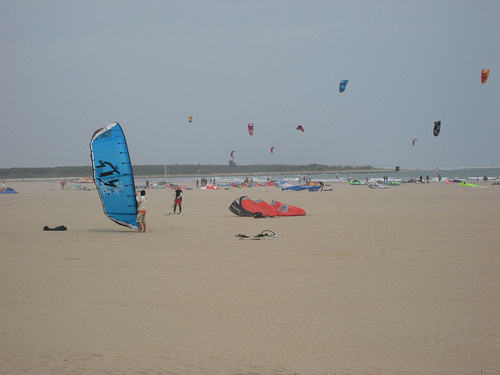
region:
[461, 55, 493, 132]
Large kite flying in sky.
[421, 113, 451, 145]
Large kite flying in sky.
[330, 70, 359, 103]
Large kite flying in sky.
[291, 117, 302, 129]
Large kite flying in the sky.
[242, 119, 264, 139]
Large kite flying in the sky.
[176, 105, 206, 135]
Large kite flying in the sky.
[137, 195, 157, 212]
Person wearing white shirt.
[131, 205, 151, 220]
Person wearing tan pants.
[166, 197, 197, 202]
Person wearing orange shorts.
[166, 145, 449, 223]
Many people on beach flying kites.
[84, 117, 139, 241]
blue kite in mans hand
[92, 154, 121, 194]
black design on kite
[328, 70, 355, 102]
blue kite in sky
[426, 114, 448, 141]
black kite in sky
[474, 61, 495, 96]
orange kite in sky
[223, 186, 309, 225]
red kite on beach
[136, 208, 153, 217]
woman wears orange shorts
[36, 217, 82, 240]
black kite on beach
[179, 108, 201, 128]
yellow kite in sky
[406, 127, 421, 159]
grey kite in sky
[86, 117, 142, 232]
A large blue sail.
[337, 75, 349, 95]
A blue kite in the air.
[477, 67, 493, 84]
A red kite in the air.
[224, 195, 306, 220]
A large red sail on the ground.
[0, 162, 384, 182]
Green trees in the baclground.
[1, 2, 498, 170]
Wide clear open sky.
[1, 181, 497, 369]
Flat brown sandy beach.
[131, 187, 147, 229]
A beach-goer in a white t-shirt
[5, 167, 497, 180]
A large body of water.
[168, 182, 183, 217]
A beach-goer with a black t-shirt.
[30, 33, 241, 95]
The sky is gloomy.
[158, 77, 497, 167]
The kites are in the sky.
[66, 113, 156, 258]
The sail is blue.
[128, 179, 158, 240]
The woman is wearing a white shirt.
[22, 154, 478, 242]
The people are on the shore.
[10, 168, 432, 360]
They are on the sand.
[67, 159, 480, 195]
The water is far away.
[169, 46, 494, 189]
The kites are colorful.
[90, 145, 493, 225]
The people are flying kites.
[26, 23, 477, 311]
They are on a beach.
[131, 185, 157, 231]
a guy standing alone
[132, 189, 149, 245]
a guy standing alone